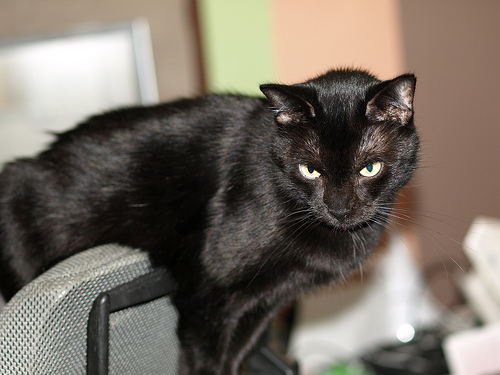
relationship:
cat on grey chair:
[3, 70, 418, 372] [0, 240, 184, 372]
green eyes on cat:
[293, 161, 382, 178] [3, 70, 418, 372]